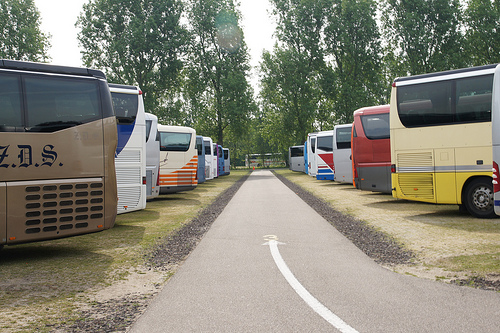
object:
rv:
[388, 62, 500, 221]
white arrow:
[258, 238, 286, 246]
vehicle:
[350, 102, 390, 195]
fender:
[354, 163, 394, 193]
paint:
[85, 142, 97, 158]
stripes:
[316, 164, 330, 169]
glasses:
[0, 166, 256, 332]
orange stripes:
[159, 181, 198, 185]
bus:
[314, 129, 337, 180]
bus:
[203, 136, 215, 181]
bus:
[197, 135, 206, 184]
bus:
[221, 147, 233, 175]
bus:
[331, 123, 356, 185]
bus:
[157, 123, 199, 194]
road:
[124, 168, 499, 332]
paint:
[317, 156, 327, 162]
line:
[267, 248, 351, 332]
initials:
[39, 144, 61, 168]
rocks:
[363, 234, 379, 247]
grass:
[271, 167, 500, 291]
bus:
[146, 111, 161, 201]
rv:
[0, 58, 120, 249]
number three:
[263, 234, 281, 240]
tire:
[461, 176, 500, 219]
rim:
[468, 214, 495, 220]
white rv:
[106, 81, 149, 215]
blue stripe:
[114, 120, 138, 159]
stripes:
[170, 169, 198, 174]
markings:
[315, 168, 332, 174]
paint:
[130, 137, 142, 146]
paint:
[149, 139, 156, 149]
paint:
[175, 157, 184, 162]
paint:
[368, 142, 377, 152]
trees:
[179, 0, 255, 146]